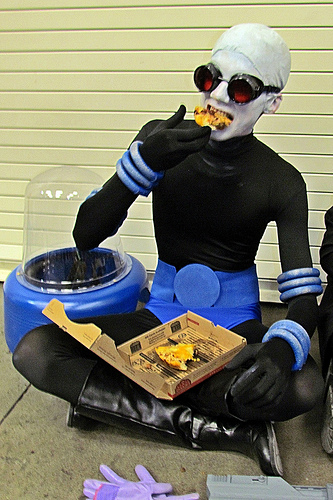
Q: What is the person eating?
A: Pizza.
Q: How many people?
A: One.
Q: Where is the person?
A: On floor.